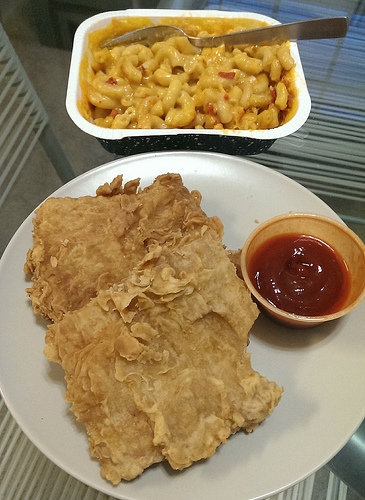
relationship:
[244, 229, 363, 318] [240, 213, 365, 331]
ketchup on cup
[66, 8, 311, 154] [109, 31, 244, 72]
bowl of food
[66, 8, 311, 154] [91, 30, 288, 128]
bowl of mac-n-cheese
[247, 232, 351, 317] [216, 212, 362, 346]
ketchup in cup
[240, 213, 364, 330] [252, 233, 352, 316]
cup of ketchup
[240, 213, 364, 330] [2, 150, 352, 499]
cup on plate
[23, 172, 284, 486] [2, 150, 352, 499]
chicken on plate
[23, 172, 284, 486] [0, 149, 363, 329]
chicken on white plate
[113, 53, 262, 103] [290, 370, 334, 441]
cheese next to plate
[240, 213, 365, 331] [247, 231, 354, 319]
cup of ketchup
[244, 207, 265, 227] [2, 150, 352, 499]
crumb on plate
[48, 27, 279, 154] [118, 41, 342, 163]
container of food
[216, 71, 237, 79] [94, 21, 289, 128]
flake in mac cheese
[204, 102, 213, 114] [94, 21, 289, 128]
flake in mac cheese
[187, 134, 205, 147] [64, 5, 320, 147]
spot on container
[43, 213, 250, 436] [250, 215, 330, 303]
chicken and ketchup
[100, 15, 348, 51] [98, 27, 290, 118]
fork in macaroni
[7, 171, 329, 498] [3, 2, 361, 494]
plate on table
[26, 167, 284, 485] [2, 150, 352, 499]
breast on plate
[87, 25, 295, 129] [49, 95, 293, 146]
macaroni in container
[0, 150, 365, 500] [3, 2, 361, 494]
plate on table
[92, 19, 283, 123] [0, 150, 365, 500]
food on plate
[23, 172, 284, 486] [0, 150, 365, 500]
chicken on plate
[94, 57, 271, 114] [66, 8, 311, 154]
macaroni in bowl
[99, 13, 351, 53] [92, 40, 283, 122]
fork in macaroni